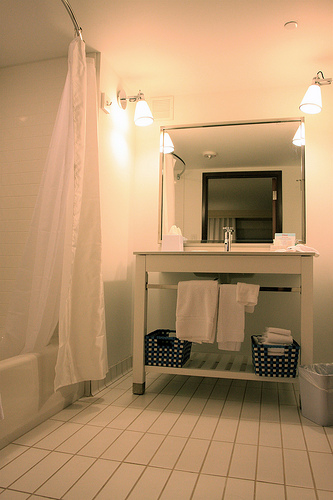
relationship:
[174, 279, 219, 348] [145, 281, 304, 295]
towel hanging on rod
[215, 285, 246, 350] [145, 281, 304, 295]
towel hanging on rod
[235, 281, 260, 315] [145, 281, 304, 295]
towel hanging on rod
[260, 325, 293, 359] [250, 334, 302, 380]
towels are in basket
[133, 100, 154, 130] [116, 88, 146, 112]
sconce has fixture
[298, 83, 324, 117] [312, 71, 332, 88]
sconce has fixture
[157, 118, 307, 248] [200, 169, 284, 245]
mirror facing door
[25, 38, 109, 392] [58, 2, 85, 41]
shower curtain on rod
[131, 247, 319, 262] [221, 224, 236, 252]
sink has hardware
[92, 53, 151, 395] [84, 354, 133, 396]
wall has baseboard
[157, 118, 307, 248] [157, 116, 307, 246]
mirror has frame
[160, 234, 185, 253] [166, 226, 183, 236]
tissue box has tissues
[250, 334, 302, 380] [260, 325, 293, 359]
basket filled with towels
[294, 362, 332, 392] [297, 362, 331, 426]
plastic bag in trash bin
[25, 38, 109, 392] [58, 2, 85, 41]
shower curtain hung on rod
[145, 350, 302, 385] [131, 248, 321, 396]
shelf in sink stand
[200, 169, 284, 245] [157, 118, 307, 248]
door in mirror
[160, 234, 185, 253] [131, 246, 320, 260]
tissue box sitting on countertop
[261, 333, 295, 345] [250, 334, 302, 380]
bath towel in basket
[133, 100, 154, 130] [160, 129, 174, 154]
sconce has reflection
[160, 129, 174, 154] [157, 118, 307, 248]
reflection in mirror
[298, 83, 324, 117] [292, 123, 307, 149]
sconce has reflection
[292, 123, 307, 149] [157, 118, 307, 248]
reflection in mirror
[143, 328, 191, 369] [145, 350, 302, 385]
basket on shelf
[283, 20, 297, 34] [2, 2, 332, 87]
smoke alarm on ceiling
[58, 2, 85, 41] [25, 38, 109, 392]
rod for shower curtain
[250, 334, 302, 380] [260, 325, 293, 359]
basket full of towels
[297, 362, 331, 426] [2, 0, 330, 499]
trash bin in bathroom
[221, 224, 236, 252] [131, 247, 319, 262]
faucet on sink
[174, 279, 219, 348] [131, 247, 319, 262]
towel hanging under sink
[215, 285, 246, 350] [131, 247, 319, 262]
towel hanging under sink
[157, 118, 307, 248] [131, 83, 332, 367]
mirror on wall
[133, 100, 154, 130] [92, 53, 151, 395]
sconce hanging on wall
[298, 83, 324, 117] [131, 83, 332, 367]
sconce hanging on wall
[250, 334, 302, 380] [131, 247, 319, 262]
basket under sink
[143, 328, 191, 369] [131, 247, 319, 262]
basket under sink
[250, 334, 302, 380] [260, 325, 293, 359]
basket has towels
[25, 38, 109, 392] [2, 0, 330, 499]
shower curtain in bathroom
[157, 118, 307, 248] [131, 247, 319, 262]
mirror over sink